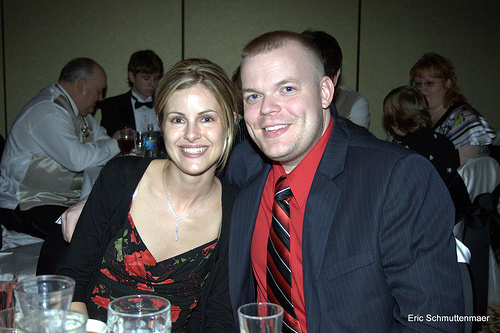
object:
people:
[0, 31, 496, 332]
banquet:
[0, 122, 499, 331]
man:
[54, 29, 466, 331]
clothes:
[218, 111, 466, 333]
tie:
[266, 174, 302, 333]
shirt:
[249, 117, 334, 333]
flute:
[236, 301, 287, 332]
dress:
[88, 209, 219, 329]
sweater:
[47, 155, 246, 333]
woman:
[57, 58, 246, 332]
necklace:
[159, 156, 219, 243]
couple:
[50, 31, 466, 333]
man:
[1, 56, 132, 291]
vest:
[0, 83, 96, 213]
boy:
[92, 47, 165, 137]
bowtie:
[128, 92, 155, 109]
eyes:
[246, 85, 298, 102]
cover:
[456, 155, 500, 202]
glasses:
[0, 275, 179, 333]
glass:
[115, 126, 136, 154]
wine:
[116, 135, 135, 153]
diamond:
[174, 232, 179, 241]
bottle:
[139, 124, 157, 159]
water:
[143, 124, 157, 156]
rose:
[123, 249, 156, 280]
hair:
[240, 31, 327, 83]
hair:
[152, 56, 240, 177]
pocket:
[320, 246, 389, 329]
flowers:
[103, 233, 175, 292]